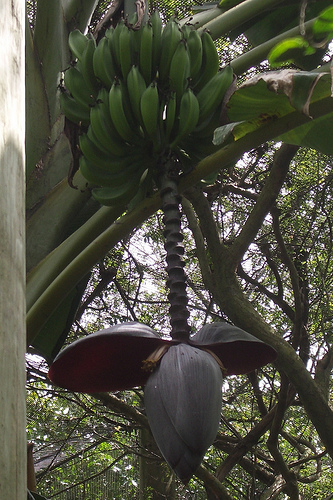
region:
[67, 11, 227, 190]
a bunch of green bananas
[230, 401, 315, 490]
the brown branches in the tree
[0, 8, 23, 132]
the sun shining on the wood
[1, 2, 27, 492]
the long piece of wood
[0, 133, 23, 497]
the shadow on the wood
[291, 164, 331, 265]
the leaves on the tree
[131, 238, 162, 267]
part of the sky through the leaves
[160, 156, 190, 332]
the long piece of tree under the green bananas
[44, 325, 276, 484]
the large part hanging from the green banana bunch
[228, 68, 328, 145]
a large banana leaf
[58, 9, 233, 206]
A large bunch of green bananas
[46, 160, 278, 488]
A large pod having from a bunch of bananas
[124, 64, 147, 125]
A green banana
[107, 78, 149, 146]
A large, green banana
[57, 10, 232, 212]
Many green bananas growing on a tree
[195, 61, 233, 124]
A large green banana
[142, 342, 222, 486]
A large seed hanging from a banana tree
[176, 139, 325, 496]
Twisting tree branches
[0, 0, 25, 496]
The trunk of a banana tree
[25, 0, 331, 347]
Banana tree branches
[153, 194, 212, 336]
large spiny stem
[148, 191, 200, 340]
the stem is thick and dark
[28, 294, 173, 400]
large and dark petal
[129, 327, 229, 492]
petal is faced downward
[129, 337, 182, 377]
light brown part of the plant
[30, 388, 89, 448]
green leaves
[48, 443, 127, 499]
skinny brown branch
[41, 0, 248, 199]
green bananas on the tree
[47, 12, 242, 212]
large group of bananas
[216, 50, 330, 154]
large green leaf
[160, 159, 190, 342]
the ribbed stem of a large dark plant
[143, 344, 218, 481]
the giant bud of a large dark plant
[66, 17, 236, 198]
a bunch of unripened green bananas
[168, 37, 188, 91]
an unripened green banana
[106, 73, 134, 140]
an unripened green banana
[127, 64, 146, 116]
an unripened green banana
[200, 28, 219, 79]
an unripened green banana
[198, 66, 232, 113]
an unripened green banana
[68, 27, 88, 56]
an unripened green banana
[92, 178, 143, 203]
an unripened green banana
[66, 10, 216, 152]
bunch of green bananas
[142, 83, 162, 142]
single green banana in bunch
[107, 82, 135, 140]
single green banana in bunch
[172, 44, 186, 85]
single green banana in bunch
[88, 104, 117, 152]
single green banana in bunch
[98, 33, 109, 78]
single green banana in bunch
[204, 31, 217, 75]
single green banana in bunch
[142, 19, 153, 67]
single green banana in bunch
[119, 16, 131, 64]
single green banana in bunch